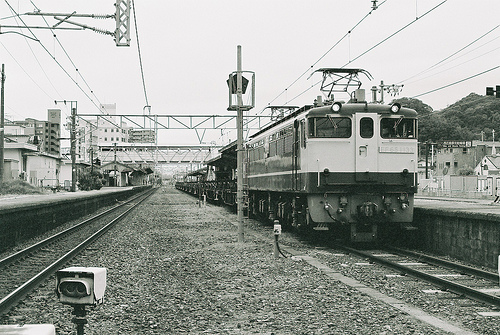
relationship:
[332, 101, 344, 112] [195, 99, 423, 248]
headlight on cable car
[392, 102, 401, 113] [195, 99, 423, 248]
headlight on cable car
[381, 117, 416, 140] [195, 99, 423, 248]
window on cable car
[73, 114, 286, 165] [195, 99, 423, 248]
bridge above cable car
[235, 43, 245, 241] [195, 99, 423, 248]
pole near cable car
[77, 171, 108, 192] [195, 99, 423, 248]
bush near cable car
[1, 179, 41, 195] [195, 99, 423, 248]
bush near cable car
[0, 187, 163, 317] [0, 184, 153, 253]
tracks near wall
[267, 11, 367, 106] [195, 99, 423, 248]
wire above cable car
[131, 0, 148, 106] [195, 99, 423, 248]
wire above cable car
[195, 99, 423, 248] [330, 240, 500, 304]
cable car on rail guage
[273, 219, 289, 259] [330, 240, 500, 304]
electric outlet near rail guage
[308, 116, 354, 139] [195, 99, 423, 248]
window on cable car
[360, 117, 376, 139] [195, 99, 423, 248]
window on cable car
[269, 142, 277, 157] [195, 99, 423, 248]
window on cable car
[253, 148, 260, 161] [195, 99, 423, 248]
window on cable car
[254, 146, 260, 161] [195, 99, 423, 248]
window on cable car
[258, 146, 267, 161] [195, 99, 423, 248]
window on cable car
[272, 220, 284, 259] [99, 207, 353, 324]
pole sticking from ground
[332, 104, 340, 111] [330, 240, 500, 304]
headlight next to rail guage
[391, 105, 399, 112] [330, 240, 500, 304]
headlight next to rail guage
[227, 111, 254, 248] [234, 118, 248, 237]
pole with a staircase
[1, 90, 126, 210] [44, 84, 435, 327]
houses beside railway station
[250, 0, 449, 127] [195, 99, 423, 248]
wire above cable car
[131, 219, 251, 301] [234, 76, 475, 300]
gravel near train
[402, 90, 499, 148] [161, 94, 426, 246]
trees behind train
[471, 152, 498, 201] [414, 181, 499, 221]
house on road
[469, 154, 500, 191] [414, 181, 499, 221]
house on road